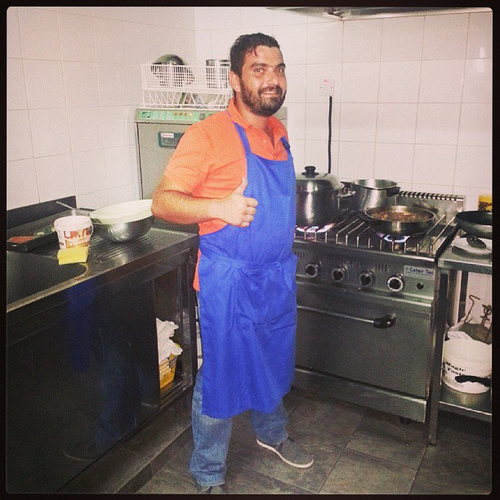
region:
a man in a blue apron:
[174, 29, 306, 496]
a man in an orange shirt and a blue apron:
[147, 21, 327, 454]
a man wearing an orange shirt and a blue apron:
[168, 38, 339, 487]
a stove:
[255, 183, 480, 395]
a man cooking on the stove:
[165, 17, 460, 462]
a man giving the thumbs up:
[145, 20, 370, 485]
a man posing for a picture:
[156, 18, 351, 473]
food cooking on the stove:
[261, 152, 451, 279]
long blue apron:
[191, 120, 311, 426]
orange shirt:
[149, 109, 306, 249]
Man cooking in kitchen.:
[146, 31, 328, 496]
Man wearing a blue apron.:
[188, 113, 317, 425]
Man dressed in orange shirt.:
[147, 93, 314, 291]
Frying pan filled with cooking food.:
[309, 201, 461, 249]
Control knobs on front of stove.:
[302, 257, 423, 300]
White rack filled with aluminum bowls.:
[136, 60, 239, 111]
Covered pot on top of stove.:
[296, 163, 349, 229]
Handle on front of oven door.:
[302, 295, 403, 335]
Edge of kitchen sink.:
[11, 248, 101, 317]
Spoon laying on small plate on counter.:
[440, 229, 499, 266]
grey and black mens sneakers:
[230, 441, 310, 483]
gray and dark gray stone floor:
[326, 422, 401, 478]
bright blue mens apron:
[192, 168, 297, 425]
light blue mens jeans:
[191, 411, 244, 476]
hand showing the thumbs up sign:
[226, 169, 268, 237]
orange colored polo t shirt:
[189, 106, 261, 202]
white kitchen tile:
[350, 53, 465, 174]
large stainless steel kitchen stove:
[313, 182, 447, 390]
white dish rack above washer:
[149, 59, 233, 108]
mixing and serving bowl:
[75, 181, 147, 244]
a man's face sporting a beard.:
[225, 35, 293, 120]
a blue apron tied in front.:
[161, 91, 298, 416]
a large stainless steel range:
[304, 171, 459, 431]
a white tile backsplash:
[353, 43, 453, 185]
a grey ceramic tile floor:
[322, 418, 410, 498]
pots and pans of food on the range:
[295, 162, 445, 243]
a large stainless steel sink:
[3, 224, 116, 379]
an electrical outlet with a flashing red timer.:
[315, 71, 341, 163]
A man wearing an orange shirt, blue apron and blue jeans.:
[155, 31, 325, 486]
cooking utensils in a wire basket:
[148, 48, 228, 93]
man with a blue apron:
[165, 29, 316, 494]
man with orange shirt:
[157, 30, 314, 495]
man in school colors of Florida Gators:
[152, 30, 314, 498]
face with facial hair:
[223, 30, 295, 117]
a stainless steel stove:
[230, 172, 465, 432]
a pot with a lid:
[291, 163, 353, 225]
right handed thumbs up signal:
[212, 170, 264, 246]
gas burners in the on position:
[284, 212, 427, 254]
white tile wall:
[340, 37, 473, 128]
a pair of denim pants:
[179, 362, 294, 494]